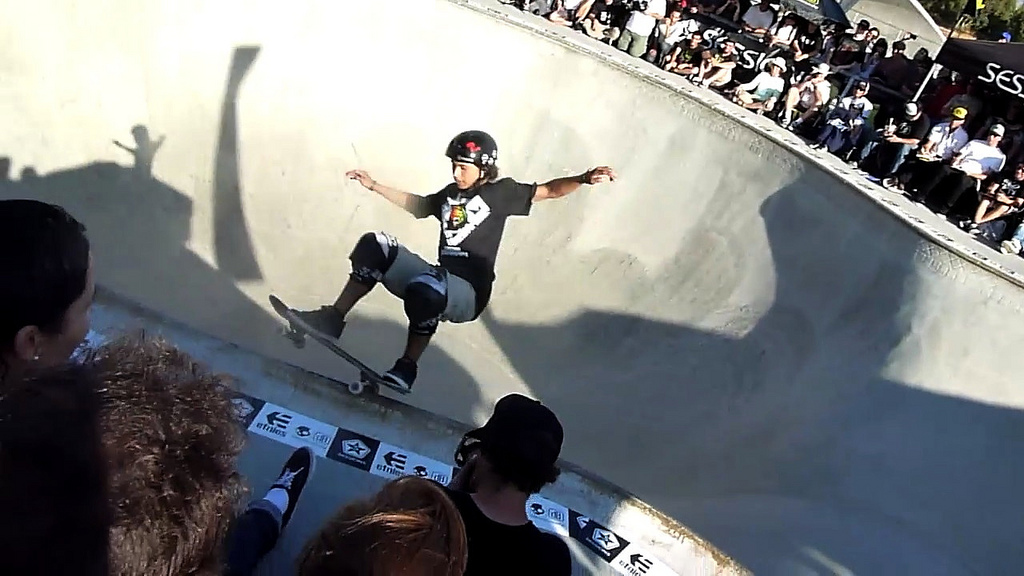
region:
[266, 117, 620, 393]
the boy riding the skateboard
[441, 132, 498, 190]
the helmet on the boy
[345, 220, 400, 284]
the right knee pad on the boy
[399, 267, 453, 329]
the left knee pad on the skater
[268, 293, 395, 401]
the skateboard under the boy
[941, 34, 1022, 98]
the black canopy on the tent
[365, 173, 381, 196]
the band on the wrist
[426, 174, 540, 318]
the black tee shirt on the boy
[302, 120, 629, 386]
person on a skateboard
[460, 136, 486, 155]
red logo on the helmet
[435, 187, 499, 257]
image on the front of the shirt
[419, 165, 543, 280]
skater's black tee shirt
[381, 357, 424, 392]
left foot on the board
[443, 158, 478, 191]
face looking at the board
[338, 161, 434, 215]
right arm held out for balance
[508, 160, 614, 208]
left arm held out for balance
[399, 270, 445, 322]
a black knee pad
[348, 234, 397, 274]
a black knee pad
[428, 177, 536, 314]
a black printed t-shirt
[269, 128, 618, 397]
a young man skateboarding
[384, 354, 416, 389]
a black and white athletic shoe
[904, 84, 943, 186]
a person watching the skateboard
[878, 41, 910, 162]
a person watching the skateboard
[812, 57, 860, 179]
a person watching the skateboard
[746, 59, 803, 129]
a person watching the skateboard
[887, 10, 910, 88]
a person watching the skateboard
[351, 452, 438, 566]
a person watching the skateboard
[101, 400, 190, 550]
a person watching the skateboard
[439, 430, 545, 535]
a person watching the skateboard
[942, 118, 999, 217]
spectator watching the skate boarder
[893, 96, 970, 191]
spectator watching the skate boarder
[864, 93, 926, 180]
spectator watching the skate boarder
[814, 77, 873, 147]
spectator watching the skate boarder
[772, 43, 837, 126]
spectator watching the skate boarder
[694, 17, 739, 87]
spectator watching the skate boarder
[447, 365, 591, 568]
spectator watching the skate boarder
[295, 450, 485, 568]
spectator watching the skate boarder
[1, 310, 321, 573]
spectator watching the skate boarder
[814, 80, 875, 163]
A person is sitting down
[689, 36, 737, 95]
A person is sitting down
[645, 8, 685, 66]
A person sitting down.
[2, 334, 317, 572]
A person sitting down.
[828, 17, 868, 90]
A person is standing up